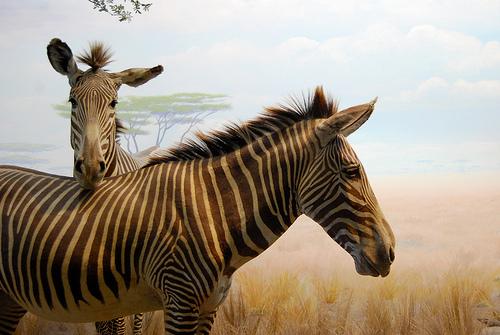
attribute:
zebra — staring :
[46, 37, 178, 333]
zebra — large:
[14, 92, 438, 331]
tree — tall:
[52, 87, 231, 174]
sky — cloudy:
[4, 0, 499, 91]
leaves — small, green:
[79, 0, 165, 36]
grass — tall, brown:
[290, 286, 402, 333]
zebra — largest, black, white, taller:
[0, 80, 442, 327]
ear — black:
[44, 40, 82, 81]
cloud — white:
[404, 71, 498, 115]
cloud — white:
[182, 3, 496, 97]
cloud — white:
[2, 128, 64, 165]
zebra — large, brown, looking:
[4, 89, 381, 334]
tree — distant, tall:
[136, 83, 248, 155]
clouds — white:
[116, 1, 476, 164]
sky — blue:
[51, 13, 446, 206]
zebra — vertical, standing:
[47, 20, 167, 212]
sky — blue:
[2, 2, 499, 182]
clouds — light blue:
[162, 7, 494, 98]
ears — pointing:
[318, 96, 381, 139]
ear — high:
[43, 34, 81, 77]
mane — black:
[141, 79, 345, 170]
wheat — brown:
[10, 261, 498, 332]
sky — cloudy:
[1, 1, 498, 164]